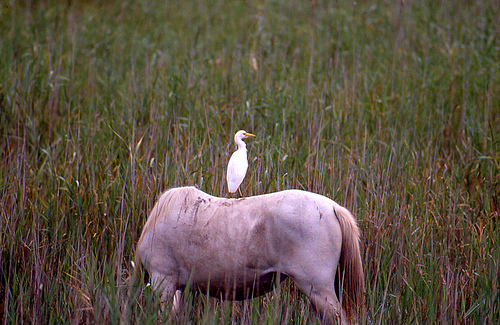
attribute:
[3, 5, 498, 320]
field — green, grassy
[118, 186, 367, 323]
horse — gray , grazing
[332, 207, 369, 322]
tail — long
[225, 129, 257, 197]
bird — very bright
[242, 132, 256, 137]
beak — yellow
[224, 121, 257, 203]
bird — white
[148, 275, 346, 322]
legs — four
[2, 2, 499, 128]
grass — tall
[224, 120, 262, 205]
bird — riding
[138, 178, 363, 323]
horse — bareback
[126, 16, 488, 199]
grass — dry, brown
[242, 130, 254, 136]
beak — yellow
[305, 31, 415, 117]
grass — light brown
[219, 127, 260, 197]
bird — tall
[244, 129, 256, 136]
beak — orange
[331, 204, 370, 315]
fur — brown